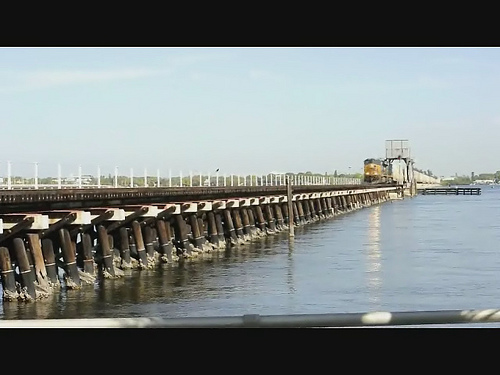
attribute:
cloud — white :
[171, 47, 253, 63]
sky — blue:
[0, 48, 499, 176]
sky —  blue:
[135, 58, 345, 143]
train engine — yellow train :
[359, 155, 389, 185]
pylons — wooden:
[57, 218, 227, 270]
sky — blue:
[8, 56, 499, 172]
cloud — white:
[390, 66, 467, 147]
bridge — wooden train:
[1, 162, 419, 295]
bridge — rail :
[2, 137, 479, 314]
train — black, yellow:
[362, 152, 402, 183]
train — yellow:
[361, 157, 388, 185]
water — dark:
[358, 210, 435, 262]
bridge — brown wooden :
[0, 179, 410, 304]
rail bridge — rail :
[6, 174, 377, 266]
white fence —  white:
[9, 166, 403, 190]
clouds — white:
[175, 79, 348, 158]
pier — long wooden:
[6, 159, 357, 297]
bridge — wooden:
[19, 159, 395, 302]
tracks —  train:
[17, 172, 285, 204]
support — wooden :
[92, 239, 205, 281]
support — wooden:
[91, 229, 199, 276]